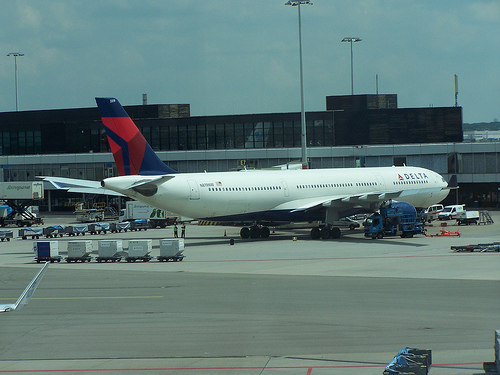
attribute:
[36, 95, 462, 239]
plane — lettered, full, white, large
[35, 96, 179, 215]
tail — blue, designed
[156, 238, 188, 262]
cart — white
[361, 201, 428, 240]
truck — blue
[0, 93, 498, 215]
airport — for landing, behind, dark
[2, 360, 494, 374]
stripe — red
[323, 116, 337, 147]
window — refletive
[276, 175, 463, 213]
wing — white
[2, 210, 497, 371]
tarmac — concrete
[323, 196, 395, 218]
engine — blue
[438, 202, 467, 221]
van — white